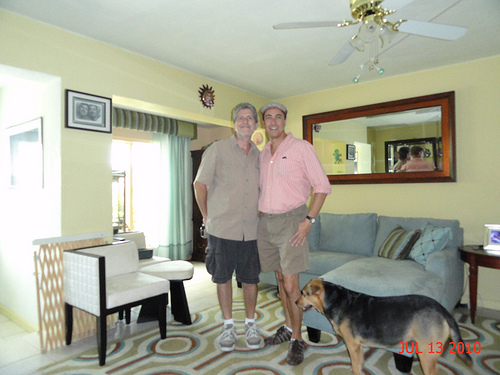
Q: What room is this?
A: It is a living room.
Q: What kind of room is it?
A: It is a living room.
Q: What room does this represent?
A: It represents the living room.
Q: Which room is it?
A: It is a living room.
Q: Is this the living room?
A: Yes, it is the living room.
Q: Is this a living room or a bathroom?
A: It is a living room.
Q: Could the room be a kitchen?
A: No, it is a living room.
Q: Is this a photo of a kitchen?
A: No, the picture is showing a living room.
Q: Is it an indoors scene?
A: Yes, it is indoors.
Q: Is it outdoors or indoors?
A: It is indoors.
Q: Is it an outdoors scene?
A: No, it is indoors.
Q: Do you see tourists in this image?
A: No, there are no tourists.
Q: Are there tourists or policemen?
A: No, there are no tourists or policemen.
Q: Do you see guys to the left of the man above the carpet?
A: Yes, there are guys to the left of the man.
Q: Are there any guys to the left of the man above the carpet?
A: Yes, there are guys to the left of the man.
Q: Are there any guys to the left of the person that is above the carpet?
A: Yes, there are guys to the left of the man.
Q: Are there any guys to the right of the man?
A: No, the guys are to the left of the man.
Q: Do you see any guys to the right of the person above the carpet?
A: No, the guys are to the left of the man.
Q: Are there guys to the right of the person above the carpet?
A: No, the guys are to the left of the man.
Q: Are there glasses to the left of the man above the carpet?
A: No, there are guys to the left of the man.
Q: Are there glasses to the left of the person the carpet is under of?
A: No, there are guys to the left of the man.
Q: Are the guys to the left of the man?
A: Yes, the guys are to the left of the man.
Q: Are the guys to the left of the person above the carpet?
A: Yes, the guys are to the left of the man.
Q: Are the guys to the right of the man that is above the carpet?
A: No, the guys are to the left of the man.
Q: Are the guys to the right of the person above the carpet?
A: No, the guys are to the left of the man.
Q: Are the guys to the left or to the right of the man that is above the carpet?
A: The guys are to the left of the man.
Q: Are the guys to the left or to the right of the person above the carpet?
A: The guys are to the left of the man.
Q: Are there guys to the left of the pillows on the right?
A: Yes, there are guys to the left of the pillows.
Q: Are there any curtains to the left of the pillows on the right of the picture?
A: No, there are guys to the left of the pillows.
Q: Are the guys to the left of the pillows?
A: Yes, the guys are to the left of the pillows.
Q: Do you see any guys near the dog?
A: Yes, there are guys near the dog.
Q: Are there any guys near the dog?
A: Yes, there are guys near the dog.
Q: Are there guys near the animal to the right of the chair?
A: Yes, there are guys near the dog.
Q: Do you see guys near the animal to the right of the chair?
A: Yes, there are guys near the dog.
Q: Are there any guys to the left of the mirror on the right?
A: Yes, there are guys to the left of the mirror.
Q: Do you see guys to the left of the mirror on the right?
A: Yes, there are guys to the left of the mirror.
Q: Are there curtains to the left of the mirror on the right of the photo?
A: No, there are guys to the left of the mirror.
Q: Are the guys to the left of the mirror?
A: Yes, the guys are to the left of the mirror.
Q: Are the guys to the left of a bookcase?
A: No, the guys are to the left of the mirror.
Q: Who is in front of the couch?
A: The guys are in front of the couch.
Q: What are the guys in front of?
A: The guys are in front of the couch.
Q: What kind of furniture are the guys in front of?
A: The guys are in front of the couch.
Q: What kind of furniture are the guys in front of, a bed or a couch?
A: The guys are in front of a couch.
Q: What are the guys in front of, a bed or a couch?
A: The guys are in front of a couch.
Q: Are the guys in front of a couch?
A: Yes, the guys are in front of a couch.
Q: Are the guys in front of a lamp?
A: No, the guys are in front of a couch.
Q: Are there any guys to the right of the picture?
A: Yes, there are guys to the right of the picture.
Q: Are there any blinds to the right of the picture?
A: No, there are guys to the right of the picture.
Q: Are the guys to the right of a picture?
A: Yes, the guys are to the right of a picture.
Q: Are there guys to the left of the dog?
A: Yes, there are guys to the left of the dog.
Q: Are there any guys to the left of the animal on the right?
A: Yes, there are guys to the left of the dog.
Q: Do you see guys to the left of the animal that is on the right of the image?
A: Yes, there are guys to the left of the dog.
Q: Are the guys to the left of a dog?
A: Yes, the guys are to the left of a dog.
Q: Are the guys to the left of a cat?
A: No, the guys are to the left of a dog.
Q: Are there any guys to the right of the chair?
A: Yes, there are guys to the right of the chair.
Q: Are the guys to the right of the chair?
A: Yes, the guys are to the right of the chair.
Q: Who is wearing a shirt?
A: The guys are wearing a shirt.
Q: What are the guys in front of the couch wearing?
A: The guys are wearing a shirt.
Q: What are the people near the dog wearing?
A: The guys are wearing a shirt.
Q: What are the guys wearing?
A: The guys are wearing a shirt.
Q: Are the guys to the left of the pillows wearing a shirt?
A: Yes, the guys are wearing a shirt.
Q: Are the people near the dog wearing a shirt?
A: Yes, the guys are wearing a shirt.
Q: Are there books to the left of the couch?
A: No, there are guys to the left of the couch.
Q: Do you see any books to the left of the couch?
A: No, there are guys to the left of the couch.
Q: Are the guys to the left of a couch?
A: Yes, the guys are to the left of a couch.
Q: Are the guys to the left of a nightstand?
A: No, the guys are to the left of a couch.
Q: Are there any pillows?
A: Yes, there are pillows.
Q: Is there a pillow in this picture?
A: Yes, there are pillows.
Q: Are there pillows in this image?
A: Yes, there are pillows.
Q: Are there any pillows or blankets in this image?
A: Yes, there are pillows.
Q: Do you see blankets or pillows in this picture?
A: Yes, there are pillows.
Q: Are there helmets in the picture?
A: No, there are no helmets.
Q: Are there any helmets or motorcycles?
A: No, there are no helmets or motorcycles.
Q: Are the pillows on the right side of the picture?
A: Yes, the pillows are on the right of the image.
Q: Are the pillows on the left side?
A: No, the pillows are on the right of the image.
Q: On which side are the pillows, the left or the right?
A: The pillows are on the right of the image.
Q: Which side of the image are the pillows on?
A: The pillows are on the right of the image.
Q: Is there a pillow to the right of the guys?
A: Yes, there are pillows to the right of the guys.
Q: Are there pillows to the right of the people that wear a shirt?
A: Yes, there are pillows to the right of the guys.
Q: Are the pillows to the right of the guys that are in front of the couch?
A: Yes, the pillows are to the right of the guys.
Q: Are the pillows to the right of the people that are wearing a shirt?
A: Yes, the pillows are to the right of the guys.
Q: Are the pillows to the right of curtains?
A: No, the pillows are to the right of the guys.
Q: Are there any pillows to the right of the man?
A: Yes, there are pillows to the right of the man.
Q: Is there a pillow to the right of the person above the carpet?
A: Yes, there are pillows to the right of the man.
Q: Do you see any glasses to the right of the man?
A: No, there are pillows to the right of the man.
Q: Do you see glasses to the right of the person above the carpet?
A: No, there are pillows to the right of the man.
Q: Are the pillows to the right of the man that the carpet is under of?
A: Yes, the pillows are to the right of the man.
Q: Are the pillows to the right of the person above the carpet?
A: Yes, the pillows are to the right of the man.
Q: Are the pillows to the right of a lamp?
A: No, the pillows are to the right of the man.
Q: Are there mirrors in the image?
A: Yes, there is a mirror.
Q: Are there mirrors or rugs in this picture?
A: Yes, there is a mirror.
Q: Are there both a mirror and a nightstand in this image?
A: No, there is a mirror but no nightstands.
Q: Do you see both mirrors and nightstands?
A: No, there is a mirror but no nightstands.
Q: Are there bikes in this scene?
A: No, there are no bikes.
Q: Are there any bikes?
A: No, there are no bikes.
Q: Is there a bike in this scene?
A: No, there are no bikes.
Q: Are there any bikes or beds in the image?
A: No, there are no bikes or beds.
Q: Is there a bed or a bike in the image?
A: No, there are no bikes or beds.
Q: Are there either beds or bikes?
A: No, there are no bikes or beds.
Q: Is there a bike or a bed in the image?
A: No, there are no bikes or beds.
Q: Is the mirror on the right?
A: Yes, the mirror is on the right of the image.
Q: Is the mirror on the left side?
A: No, the mirror is on the right of the image.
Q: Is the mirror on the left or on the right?
A: The mirror is on the right of the image.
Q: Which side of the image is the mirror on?
A: The mirror is on the right of the image.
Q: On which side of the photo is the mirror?
A: The mirror is on the right of the image.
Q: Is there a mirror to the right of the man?
A: Yes, there is a mirror to the right of the man.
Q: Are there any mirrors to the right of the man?
A: Yes, there is a mirror to the right of the man.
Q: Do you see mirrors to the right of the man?
A: Yes, there is a mirror to the right of the man.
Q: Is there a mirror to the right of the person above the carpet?
A: Yes, there is a mirror to the right of the man.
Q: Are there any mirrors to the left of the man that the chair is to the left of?
A: No, the mirror is to the right of the man.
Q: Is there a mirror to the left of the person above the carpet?
A: No, the mirror is to the right of the man.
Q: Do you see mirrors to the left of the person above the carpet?
A: No, the mirror is to the right of the man.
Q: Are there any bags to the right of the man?
A: No, there is a mirror to the right of the man.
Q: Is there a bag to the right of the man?
A: No, there is a mirror to the right of the man.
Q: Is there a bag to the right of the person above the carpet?
A: No, there is a mirror to the right of the man.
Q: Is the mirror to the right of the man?
A: Yes, the mirror is to the right of the man.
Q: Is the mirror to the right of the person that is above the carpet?
A: Yes, the mirror is to the right of the man.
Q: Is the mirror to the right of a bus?
A: No, the mirror is to the right of the man.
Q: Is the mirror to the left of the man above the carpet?
A: No, the mirror is to the right of the man.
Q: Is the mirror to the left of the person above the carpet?
A: No, the mirror is to the right of the man.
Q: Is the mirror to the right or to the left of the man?
A: The mirror is to the right of the man.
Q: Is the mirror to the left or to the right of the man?
A: The mirror is to the right of the man.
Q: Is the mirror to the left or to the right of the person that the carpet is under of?
A: The mirror is to the right of the man.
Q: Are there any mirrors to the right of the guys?
A: Yes, there is a mirror to the right of the guys.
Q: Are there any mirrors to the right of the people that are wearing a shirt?
A: Yes, there is a mirror to the right of the guys.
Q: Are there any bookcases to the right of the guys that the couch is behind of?
A: No, there is a mirror to the right of the guys.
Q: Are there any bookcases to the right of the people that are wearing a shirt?
A: No, there is a mirror to the right of the guys.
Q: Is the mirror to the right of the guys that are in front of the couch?
A: Yes, the mirror is to the right of the guys.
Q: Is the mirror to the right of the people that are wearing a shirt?
A: Yes, the mirror is to the right of the guys.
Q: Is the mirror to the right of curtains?
A: No, the mirror is to the right of the guys.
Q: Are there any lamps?
A: No, there are no lamps.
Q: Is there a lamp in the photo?
A: No, there are no lamps.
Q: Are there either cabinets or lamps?
A: No, there are no lamps or cabinets.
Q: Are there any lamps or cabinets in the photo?
A: No, there are no lamps or cabinets.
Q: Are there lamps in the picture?
A: No, there are no lamps.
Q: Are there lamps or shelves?
A: No, there are no lamps or shelves.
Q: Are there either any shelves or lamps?
A: No, there are no lamps or shelves.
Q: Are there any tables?
A: Yes, there is a table.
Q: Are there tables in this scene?
A: Yes, there is a table.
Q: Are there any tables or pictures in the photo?
A: Yes, there is a table.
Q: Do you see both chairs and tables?
A: Yes, there are both a table and a chair.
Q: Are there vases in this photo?
A: No, there are no vases.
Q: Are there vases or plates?
A: No, there are no vases or plates.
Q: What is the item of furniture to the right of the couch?
A: The piece of furniture is a table.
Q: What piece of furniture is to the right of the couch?
A: The piece of furniture is a table.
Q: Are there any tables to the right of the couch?
A: Yes, there is a table to the right of the couch.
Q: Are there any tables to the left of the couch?
A: No, the table is to the right of the couch.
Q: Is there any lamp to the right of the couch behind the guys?
A: No, there is a table to the right of the couch.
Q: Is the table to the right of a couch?
A: Yes, the table is to the right of a couch.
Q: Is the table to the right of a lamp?
A: No, the table is to the right of a couch.